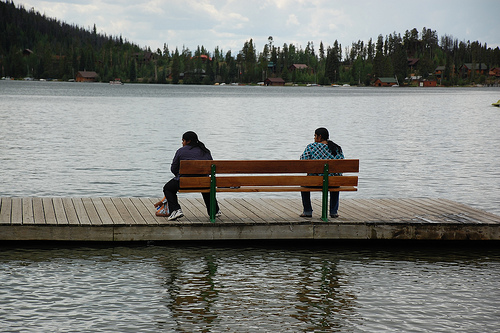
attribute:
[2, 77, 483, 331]
water — CRYSTAL, CLEAR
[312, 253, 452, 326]
water — rippled